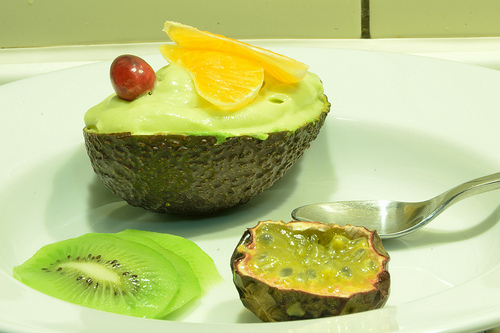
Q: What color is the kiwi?
A: Green.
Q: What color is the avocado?
A: Green.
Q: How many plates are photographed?
A: 1.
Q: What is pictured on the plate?
A: Fruits.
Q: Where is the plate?
A: Table.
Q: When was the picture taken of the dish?
A: Early morning.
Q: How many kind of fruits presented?
A: 5.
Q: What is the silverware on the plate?
A: Spoon.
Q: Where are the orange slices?
A: Top of the avocado.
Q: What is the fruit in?
A: Avocado skin.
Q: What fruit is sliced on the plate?
A: Kiwi.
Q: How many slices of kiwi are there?
A: Three.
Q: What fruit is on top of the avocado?
A: Oranges and grape.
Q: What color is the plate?
A: White.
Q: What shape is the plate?
A: Round.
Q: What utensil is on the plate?
A: Spoon.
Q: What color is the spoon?
A: Silver.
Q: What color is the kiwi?
A: Green.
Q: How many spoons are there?
A: One.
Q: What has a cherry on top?
A: Avocado.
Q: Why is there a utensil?
A: To pick up food.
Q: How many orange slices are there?
A: 2.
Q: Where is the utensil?
A: On plate.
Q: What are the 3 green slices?
A: Kiwi.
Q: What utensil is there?
A: Spoon.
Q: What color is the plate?
A: White.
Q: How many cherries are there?
A: 1.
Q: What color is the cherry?
A: Red.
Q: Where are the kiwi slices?
A: Front left.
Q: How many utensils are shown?
A: 1.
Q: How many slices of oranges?
A: 2.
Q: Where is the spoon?
A: In the bowl.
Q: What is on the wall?
A: Off-white tile.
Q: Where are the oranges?
A: On top the avocado.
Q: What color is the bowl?
A: White.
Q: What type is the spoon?
A: Stainless steel.